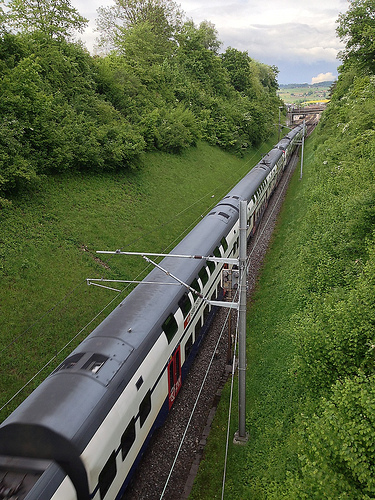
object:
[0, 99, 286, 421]
hill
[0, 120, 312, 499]
train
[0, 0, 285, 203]
trees